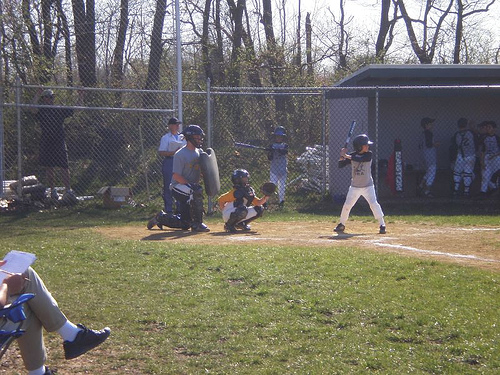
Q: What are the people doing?
A: Playing baseball.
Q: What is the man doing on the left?
A: Sitting.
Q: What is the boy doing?
A: Batting.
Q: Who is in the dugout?
A: 3 boys.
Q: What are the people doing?
A: Playing baseball.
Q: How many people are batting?
A: 1.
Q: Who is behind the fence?
A: A man.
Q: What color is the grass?
A: Green.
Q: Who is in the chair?
A: The coach.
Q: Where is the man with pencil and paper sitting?
A: In a chair.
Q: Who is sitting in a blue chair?
A: A man.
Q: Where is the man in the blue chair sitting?
A: On a baseball field.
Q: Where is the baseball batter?
A: At home plate.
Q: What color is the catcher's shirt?
A: Yellow.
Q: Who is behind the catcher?
A: The umpire.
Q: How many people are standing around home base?
A: Three.